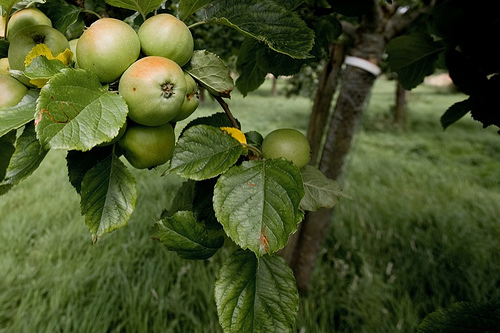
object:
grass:
[352, 276, 380, 332]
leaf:
[212, 158, 306, 260]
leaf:
[160, 123, 243, 180]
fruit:
[118, 55, 188, 126]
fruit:
[76, 18, 139, 83]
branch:
[215, 96, 240, 130]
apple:
[139, 13, 194, 65]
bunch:
[75, 13, 202, 170]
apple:
[260, 129, 311, 173]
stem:
[32, 33, 44, 45]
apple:
[6, 24, 70, 89]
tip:
[252, 254, 262, 269]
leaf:
[33, 68, 129, 152]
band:
[342, 53, 382, 77]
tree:
[0, 0, 499, 296]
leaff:
[215, 126, 247, 144]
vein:
[264, 200, 280, 217]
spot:
[132, 86, 137, 91]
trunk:
[274, 35, 386, 298]